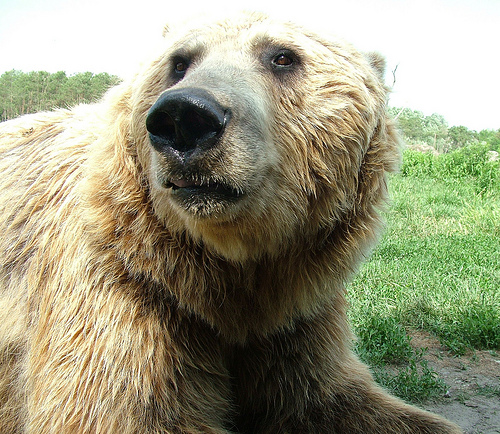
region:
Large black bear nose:
[139, 86, 246, 160]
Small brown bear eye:
[255, 28, 319, 95]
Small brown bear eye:
[147, 42, 207, 87]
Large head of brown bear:
[117, 10, 424, 260]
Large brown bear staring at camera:
[2, 11, 464, 432]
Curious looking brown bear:
[6, 12, 418, 432]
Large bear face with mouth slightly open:
[98, 6, 413, 268]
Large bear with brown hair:
[0, 25, 418, 427]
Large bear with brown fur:
[0, 13, 412, 433]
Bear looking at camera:
[0, 12, 461, 427]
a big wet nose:
[136, 87, 230, 151]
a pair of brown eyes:
[161, 47, 305, 77]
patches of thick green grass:
[414, 187, 489, 359]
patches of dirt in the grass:
[409, 305, 499, 367]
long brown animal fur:
[94, 230, 234, 420]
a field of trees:
[4, 58, 74, 112]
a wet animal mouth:
[132, 163, 253, 212]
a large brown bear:
[17, 20, 482, 417]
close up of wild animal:
[49, 22, 480, 424]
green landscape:
[9, 16, 491, 344]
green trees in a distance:
[1, 65, 118, 122]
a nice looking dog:
[1, 0, 461, 427]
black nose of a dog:
[142, 82, 225, 147]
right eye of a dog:
[264, 43, 300, 74]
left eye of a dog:
[165, 45, 189, 72]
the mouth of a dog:
[161, 163, 257, 223]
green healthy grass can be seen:
[347, 145, 498, 410]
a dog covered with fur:
[0, 10, 450, 432]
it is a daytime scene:
[1, 0, 498, 432]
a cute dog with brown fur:
[2, 20, 458, 430]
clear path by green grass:
[403, 325, 461, 375]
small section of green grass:
[382, 362, 452, 407]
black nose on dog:
[137, 86, 239, 153]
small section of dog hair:
[84, 199, 121, 244]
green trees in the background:
[4, 62, 96, 96]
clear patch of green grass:
[412, 207, 465, 239]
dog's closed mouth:
[136, 167, 253, 216]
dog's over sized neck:
[102, 171, 369, 328]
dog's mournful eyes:
[254, 40, 315, 85]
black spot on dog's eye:
[261, 44, 272, 64]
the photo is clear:
[5, 5, 496, 432]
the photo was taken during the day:
[6, 5, 473, 427]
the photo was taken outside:
[6, 1, 470, 431]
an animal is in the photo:
[0, 5, 468, 429]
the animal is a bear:
[6, 6, 458, 431]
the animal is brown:
[8, 2, 423, 432]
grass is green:
[406, 169, 496, 346]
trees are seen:
[0, 68, 141, 114]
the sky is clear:
[9, 2, 499, 69]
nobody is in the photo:
[4, 5, 487, 432]